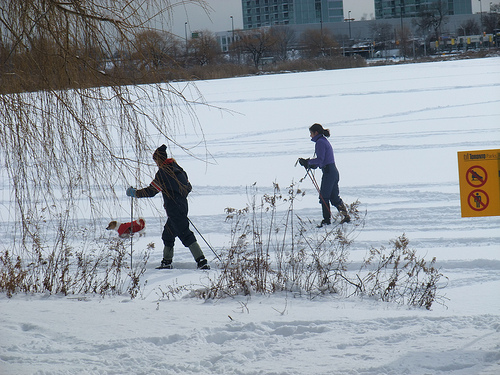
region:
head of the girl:
[302, 120, 357, 151]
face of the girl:
[146, 130, 181, 168]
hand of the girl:
[280, 128, 337, 190]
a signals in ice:
[451, 122, 496, 208]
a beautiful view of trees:
[56, 218, 494, 329]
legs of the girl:
[314, 177, 386, 229]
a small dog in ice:
[91, 210, 165, 250]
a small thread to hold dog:
[116, 205, 157, 217]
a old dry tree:
[0, 8, 171, 214]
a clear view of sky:
[18, 65, 453, 367]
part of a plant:
[273, 232, 306, 274]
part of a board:
[459, 196, 481, 219]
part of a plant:
[280, 215, 337, 277]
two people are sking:
[61, 49, 378, 321]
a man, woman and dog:
[80, 85, 360, 337]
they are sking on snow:
[61, 63, 452, 297]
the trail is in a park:
[18, 21, 480, 316]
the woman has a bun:
[277, 116, 358, 231]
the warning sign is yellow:
[434, 92, 498, 224]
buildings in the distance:
[71, 16, 423, 311]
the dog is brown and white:
[94, 211, 154, 224]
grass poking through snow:
[40, 63, 454, 360]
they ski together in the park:
[68, 90, 417, 251]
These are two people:
[124, 106, 366, 246]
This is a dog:
[128, 205, 153, 229]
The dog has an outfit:
[124, 188, 154, 291]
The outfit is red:
[94, 193, 146, 232]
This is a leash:
[302, 178, 320, 192]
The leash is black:
[260, 128, 304, 208]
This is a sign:
[443, 149, 496, 203]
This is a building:
[226, 26, 386, 81]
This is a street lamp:
[215, 3, 262, 42]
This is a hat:
[134, 109, 221, 179]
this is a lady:
[309, 111, 360, 213]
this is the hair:
[316, 123, 331, 136]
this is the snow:
[261, 315, 404, 356]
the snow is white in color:
[283, 304, 341, 359]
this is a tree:
[305, 34, 350, 64]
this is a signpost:
[452, 141, 493, 223]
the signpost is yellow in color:
[481, 158, 499, 186]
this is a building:
[244, 8, 345, 21]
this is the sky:
[186, 12, 231, 20]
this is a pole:
[224, 14, 240, 49]